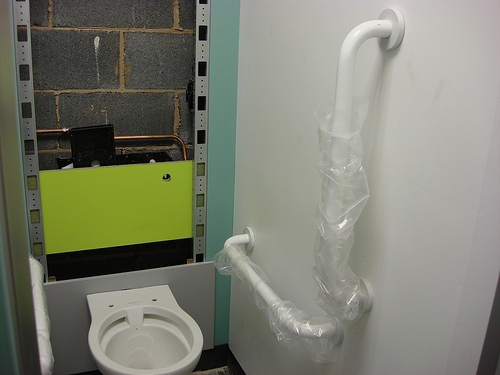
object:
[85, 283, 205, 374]
toilet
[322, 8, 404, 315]
bar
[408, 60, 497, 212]
wall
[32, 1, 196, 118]
wall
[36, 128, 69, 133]
pipe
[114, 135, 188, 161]
pipe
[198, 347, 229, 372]
strip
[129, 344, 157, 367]
water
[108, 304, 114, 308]
lid hole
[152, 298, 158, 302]
lid hole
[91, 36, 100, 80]
paint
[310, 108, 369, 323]
plastic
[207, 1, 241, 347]
board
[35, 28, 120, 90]
block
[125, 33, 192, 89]
block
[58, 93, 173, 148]
block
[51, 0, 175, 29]
block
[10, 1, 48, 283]
beam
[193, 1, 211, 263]
beam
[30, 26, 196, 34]
grout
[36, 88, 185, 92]
grout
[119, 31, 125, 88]
grout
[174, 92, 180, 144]
grout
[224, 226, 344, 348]
handle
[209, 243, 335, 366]
plastic covering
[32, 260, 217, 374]
panel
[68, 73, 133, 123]
panel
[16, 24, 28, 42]
cutout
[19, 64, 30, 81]
cutout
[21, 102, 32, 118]
cutout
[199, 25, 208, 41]
cutout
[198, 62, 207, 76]
cutout